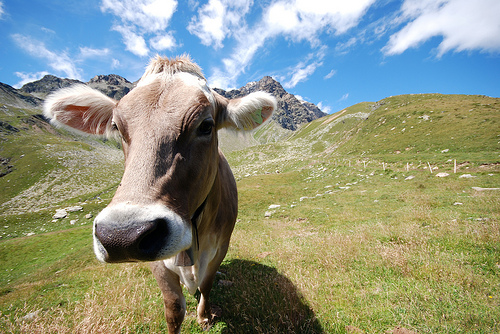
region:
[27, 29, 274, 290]
brown and white cow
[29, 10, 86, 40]
white clouds in blue sky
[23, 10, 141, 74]
white clouds in blue sky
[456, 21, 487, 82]
white clouds in blue sky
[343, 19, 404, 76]
white clouds in blue sky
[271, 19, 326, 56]
white clouds in blue sky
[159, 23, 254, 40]
white clouds in blue sky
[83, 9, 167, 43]
white clouds in blue sky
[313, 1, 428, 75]
white clouds in blue sky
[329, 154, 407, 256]
short green grass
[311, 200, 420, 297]
brown and green grass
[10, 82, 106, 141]
ear of brown cow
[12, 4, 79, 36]
light and dark green grass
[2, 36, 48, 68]
light and dark green grass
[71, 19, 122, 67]
light and dark green grass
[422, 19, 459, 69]
light and dark green grass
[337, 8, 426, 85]
light and dark green grass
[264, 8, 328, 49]
light and dark green grass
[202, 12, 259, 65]
light and dark green grass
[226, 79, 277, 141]
left ear of cow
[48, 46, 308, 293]
the cow is brown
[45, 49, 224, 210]
the cow is brown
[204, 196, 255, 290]
the cow is brown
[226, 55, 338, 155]
mountain in the distance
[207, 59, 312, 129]
mountain in the distance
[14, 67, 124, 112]
mountain in the distance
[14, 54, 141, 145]
mountain in the distance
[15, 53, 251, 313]
brown cow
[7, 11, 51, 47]
white clouds in blue sky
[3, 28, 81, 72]
white clouds in blue sky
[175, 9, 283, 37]
white clouds in blue sky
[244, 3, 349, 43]
white clouds in blue sky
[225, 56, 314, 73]
white clouds in blue sky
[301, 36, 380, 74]
white clouds in blue sky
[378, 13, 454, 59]
white clouds in blue sky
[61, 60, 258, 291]
cow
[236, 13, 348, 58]
white clouds in sky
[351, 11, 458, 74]
white clouds in sky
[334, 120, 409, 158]
short green and brown grass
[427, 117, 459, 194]
short green and brown grass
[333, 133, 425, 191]
short green and brown grass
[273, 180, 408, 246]
short green and brown grass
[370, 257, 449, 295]
short green and brown grass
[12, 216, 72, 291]
short green and brown grass